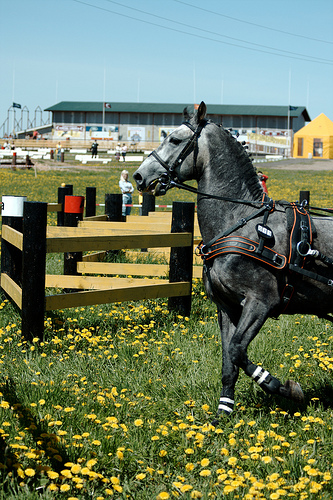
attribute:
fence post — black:
[22, 199, 48, 338]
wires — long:
[85, 0, 330, 67]